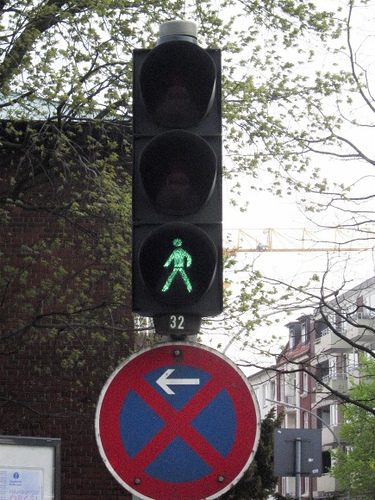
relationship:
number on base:
[165, 312, 190, 340] [132, 49, 220, 337]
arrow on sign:
[154, 365, 202, 395] [94, 340, 260, 499]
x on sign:
[127, 373, 227, 474] [94, 340, 260, 499]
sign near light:
[94, 340, 260, 499] [129, 47, 223, 337]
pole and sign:
[293, 437, 305, 500] [276, 428, 322, 478]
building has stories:
[278, 277, 375, 484] [307, 326, 355, 444]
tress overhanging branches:
[6, 5, 129, 365] [278, 112, 374, 410]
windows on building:
[285, 318, 313, 350] [278, 277, 375, 484]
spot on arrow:
[163, 371, 170, 378] [154, 365, 202, 395]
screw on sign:
[172, 349, 181, 359] [94, 340, 260, 499]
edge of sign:
[91, 367, 109, 479] [94, 340, 260, 499]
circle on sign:
[121, 365, 235, 485] [94, 340, 260, 499]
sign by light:
[1, 436, 64, 499] [129, 47, 223, 337]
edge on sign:
[52, 439, 64, 500] [1, 436, 64, 499]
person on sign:
[160, 230, 194, 294] [94, 340, 260, 499]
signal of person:
[128, 217, 222, 318] [160, 230, 194, 294]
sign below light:
[94, 340, 260, 499] [129, 47, 223, 337]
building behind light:
[278, 277, 375, 484] [129, 47, 223, 337]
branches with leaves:
[278, 112, 374, 410] [223, 255, 332, 369]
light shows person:
[150, 231, 205, 303] [160, 230, 194, 294]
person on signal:
[160, 230, 194, 294] [128, 217, 222, 318]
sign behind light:
[276, 428, 322, 478] [129, 47, 223, 337]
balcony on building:
[318, 323, 351, 351] [278, 277, 375, 484]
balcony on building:
[347, 312, 375, 337] [278, 277, 375, 484]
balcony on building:
[316, 373, 350, 412] [278, 277, 375, 484]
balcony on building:
[322, 420, 355, 445] [278, 277, 375, 484]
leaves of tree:
[223, 255, 332, 369] [1, 2, 131, 350]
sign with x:
[94, 340, 260, 499] [127, 373, 227, 474]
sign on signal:
[94, 340, 260, 499] [132, 49, 220, 337]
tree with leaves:
[1, 2, 131, 350] [223, 255, 332, 369]